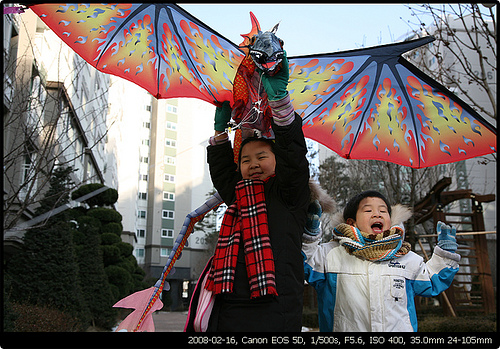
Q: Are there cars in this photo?
A: No, there are no cars.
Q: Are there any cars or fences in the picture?
A: No, there are no cars or fences.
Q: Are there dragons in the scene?
A: Yes, there is a dragon.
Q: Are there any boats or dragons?
A: Yes, there is a dragon.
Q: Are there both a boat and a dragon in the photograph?
A: No, there is a dragon but no boats.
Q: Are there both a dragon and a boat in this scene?
A: No, there is a dragon but no boats.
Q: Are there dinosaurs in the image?
A: No, there are no dinosaurs.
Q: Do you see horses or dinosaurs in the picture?
A: No, there are no dinosaurs or horses.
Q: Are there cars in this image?
A: No, there are no cars.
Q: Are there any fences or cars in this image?
A: No, there are no cars or fences.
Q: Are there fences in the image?
A: No, there are no fences.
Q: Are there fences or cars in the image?
A: No, there are no fences or cars.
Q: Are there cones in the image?
A: No, there are no cones.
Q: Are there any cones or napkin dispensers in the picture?
A: No, there are no cones or napkin dispensers.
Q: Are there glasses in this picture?
A: No, there are no glasses.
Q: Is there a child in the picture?
A: Yes, there is a child.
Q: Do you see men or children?
A: Yes, there is a child.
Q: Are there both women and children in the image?
A: No, there is a child but no women.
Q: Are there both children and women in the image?
A: No, there is a child but no women.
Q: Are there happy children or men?
A: Yes, there is a happy child.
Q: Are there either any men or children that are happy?
A: Yes, the child is happy.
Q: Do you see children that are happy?
A: Yes, there is a happy child.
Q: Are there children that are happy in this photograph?
A: Yes, there is a happy child.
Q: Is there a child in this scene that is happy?
A: Yes, there is a child that is happy.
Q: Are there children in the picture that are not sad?
A: Yes, there is a happy child.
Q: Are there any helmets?
A: No, there are no helmets.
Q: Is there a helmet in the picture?
A: No, there are no helmets.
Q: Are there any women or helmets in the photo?
A: No, there are no helmets or women.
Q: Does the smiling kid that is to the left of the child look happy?
A: Yes, the kid is happy.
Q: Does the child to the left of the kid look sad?
A: No, the kid is happy.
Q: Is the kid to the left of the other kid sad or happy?
A: The kid is happy.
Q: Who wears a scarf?
A: The child wears a scarf.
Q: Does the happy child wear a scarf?
A: Yes, the child wears a scarf.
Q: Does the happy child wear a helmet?
A: No, the kid wears a scarf.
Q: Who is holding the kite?
A: The kid is holding the kite.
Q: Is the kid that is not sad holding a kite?
A: Yes, the child is holding a kite.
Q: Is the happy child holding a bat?
A: No, the kid is holding a kite.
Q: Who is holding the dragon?
A: The kid is holding the dragon.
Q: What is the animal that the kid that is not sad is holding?
A: The animal is a dragon.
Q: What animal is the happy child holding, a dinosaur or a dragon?
A: The child is holding a dragon.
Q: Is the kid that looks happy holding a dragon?
A: Yes, the child is holding a dragon.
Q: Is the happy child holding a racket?
A: No, the kid is holding a dragon.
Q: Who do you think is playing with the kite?
A: The kid is playing with the kite.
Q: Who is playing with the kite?
A: The kid is playing with the kite.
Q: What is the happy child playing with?
A: The kid is playing with a kite.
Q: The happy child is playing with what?
A: The kid is playing with a kite.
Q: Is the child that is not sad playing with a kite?
A: Yes, the kid is playing with a kite.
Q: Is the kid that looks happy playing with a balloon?
A: No, the child is playing with a kite.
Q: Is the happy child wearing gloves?
A: Yes, the child is wearing gloves.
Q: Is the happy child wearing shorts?
A: No, the child is wearing gloves.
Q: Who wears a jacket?
A: The child wears a jacket.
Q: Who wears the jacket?
A: The child wears a jacket.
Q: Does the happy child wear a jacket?
A: Yes, the kid wears a jacket.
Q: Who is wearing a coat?
A: The kid is wearing a coat.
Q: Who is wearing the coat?
A: The kid is wearing a coat.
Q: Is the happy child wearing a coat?
A: Yes, the kid is wearing a coat.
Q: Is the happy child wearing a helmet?
A: No, the kid is wearing a coat.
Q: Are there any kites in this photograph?
A: Yes, there is a kite.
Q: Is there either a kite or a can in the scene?
A: Yes, there is a kite.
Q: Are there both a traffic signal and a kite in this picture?
A: No, there is a kite but no traffic lights.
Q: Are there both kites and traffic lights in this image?
A: No, there is a kite but no traffic lights.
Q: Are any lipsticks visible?
A: No, there are no lipsticks.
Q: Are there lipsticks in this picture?
A: No, there are no lipsticks.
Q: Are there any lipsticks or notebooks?
A: No, there are no lipsticks or notebooks.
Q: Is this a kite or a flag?
A: This is a kite.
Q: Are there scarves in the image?
A: Yes, there is a scarf.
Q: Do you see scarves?
A: Yes, there is a scarf.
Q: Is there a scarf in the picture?
A: Yes, there is a scarf.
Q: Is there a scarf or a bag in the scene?
A: Yes, there is a scarf.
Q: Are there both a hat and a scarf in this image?
A: No, there is a scarf but no hats.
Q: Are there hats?
A: No, there are no hats.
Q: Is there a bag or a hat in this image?
A: No, there are no hats or bags.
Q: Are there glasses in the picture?
A: No, there are no glasses.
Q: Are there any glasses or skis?
A: No, there are no glasses or skis.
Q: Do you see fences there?
A: No, there are no fences.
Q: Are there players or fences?
A: No, there are no fences or players.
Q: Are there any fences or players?
A: No, there are no fences or players.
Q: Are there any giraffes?
A: No, there are no giraffes.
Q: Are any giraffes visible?
A: No, there are no giraffes.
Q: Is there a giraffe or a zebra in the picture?
A: No, there are no giraffes or zebras.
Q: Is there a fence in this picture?
A: No, there are no fences.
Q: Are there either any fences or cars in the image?
A: No, there are no fences or cars.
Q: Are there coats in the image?
A: Yes, there is a coat.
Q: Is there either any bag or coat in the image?
A: Yes, there is a coat.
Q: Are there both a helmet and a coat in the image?
A: No, there is a coat but no helmets.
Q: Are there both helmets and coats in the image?
A: No, there is a coat but no helmets.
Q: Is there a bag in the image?
A: No, there are no bags.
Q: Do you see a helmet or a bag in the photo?
A: No, there are no bags or helmets.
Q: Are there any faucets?
A: No, there are no faucets.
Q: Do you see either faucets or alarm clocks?
A: No, there are no faucets or alarm clocks.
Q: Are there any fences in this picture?
A: No, there are no fences.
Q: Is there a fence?
A: No, there are no fences.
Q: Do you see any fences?
A: No, there are no fences.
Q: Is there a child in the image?
A: Yes, there is a child.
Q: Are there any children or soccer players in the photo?
A: Yes, there is a child.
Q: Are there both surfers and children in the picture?
A: No, there is a child but no surfers.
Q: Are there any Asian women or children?
A: Yes, there is an Asian child.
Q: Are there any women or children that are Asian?
A: Yes, the child is asian.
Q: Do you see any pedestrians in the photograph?
A: No, there are no pedestrians.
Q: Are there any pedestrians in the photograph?
A: No, there are no pedestrians.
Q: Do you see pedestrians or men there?
A: No, there are no pedestrians or men.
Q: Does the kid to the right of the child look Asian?
A: Yes, the kid is asian.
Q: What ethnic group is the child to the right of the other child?
A: The kid is asian.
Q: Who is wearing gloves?
A: The child is wearing gloves.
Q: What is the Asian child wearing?
A: The kid is wearing gloves.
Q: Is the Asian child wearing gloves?
A: Yes, the child is wearing gloves.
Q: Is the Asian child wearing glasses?
A: No, the kid is wearing gloves.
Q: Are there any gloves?
A: Yes, there are gloves.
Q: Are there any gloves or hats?
A: Yes, there are gloves.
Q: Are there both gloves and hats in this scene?
A: No, there are gloves but no hats.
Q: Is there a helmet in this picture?
A: No, there are no helmets.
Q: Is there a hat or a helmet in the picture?
A: No, there are no helmets or hats.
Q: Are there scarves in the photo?
A: Yes, there is a scarf.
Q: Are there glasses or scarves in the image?
A: Yes, there is a scarf.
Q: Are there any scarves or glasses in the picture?
A: Yes, there is a scarf.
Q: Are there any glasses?
A: No, there are no glasses.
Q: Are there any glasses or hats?
A: No, there are no glasses or hats.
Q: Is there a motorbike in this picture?
A: No, there are no motorcycles.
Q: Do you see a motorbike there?
A: No, there are no motorcycles.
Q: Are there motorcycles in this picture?
A: No, there are no motorcycles.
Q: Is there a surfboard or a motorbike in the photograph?
A: No, there are no motorcycles or surfboards.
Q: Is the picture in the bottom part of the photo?
A: Yes, the picture is in the bottom of the image.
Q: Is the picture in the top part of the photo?
A: No, the picture is in the bottom of the image.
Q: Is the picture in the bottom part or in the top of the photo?
A: The picture is in the bottom of the image.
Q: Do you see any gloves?
A: Yes, there are gloves.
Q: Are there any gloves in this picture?
A: Yes, there are gloves.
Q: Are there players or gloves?
A: Yes, there are gloves.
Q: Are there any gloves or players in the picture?
A: Yes, there are gloves.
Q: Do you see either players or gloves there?
A: Yes, there are gloves.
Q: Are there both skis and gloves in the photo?
A: No, there are gloves but no skis.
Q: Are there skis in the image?
A: No, there are no skis.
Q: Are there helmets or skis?
A: No, there are no skis or helmets.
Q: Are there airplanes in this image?
A: No, there are no airplanes.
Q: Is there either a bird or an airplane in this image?
A: No, there are no airplanes or birds.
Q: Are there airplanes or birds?
A: No, there are no airplanes or birds.